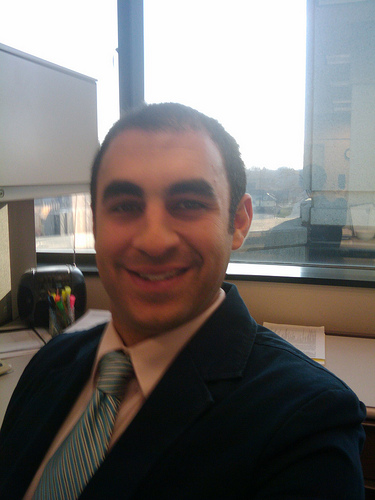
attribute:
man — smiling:
[3, 87, 374, 496]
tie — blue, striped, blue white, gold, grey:
[9, 347, 182, 498]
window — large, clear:
[126, 0, 368, 275]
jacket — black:
[2, 279, 370, 500]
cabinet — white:
[244, 323, 373, 426]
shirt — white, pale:
[17, 286, 233, 499]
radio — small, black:
[20, 256, 93, 329]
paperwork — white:
[253, 321, 341, 366]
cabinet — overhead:
[0, 51, 109, 204]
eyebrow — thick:
[165, 175, 218, 198]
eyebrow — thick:
[94, 172, 145, 201]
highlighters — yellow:
[48, 281, 79, 306]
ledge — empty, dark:
[31, 251, 371, 282]